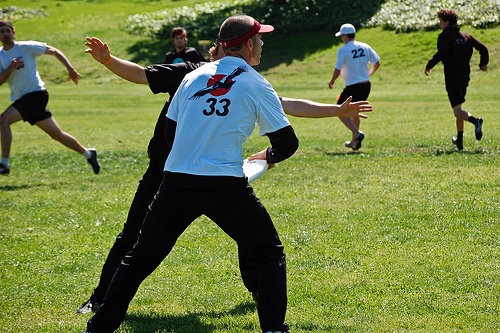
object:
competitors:
[1, 8, 474, 167]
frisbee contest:
[236, 149, 266, 179]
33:
[201, 96, 233, 118]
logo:
[186, 63, 246, 101]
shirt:
[163, 55, 292, 179]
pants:
[83, 169, 289, 331]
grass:
[1, 180, 91, 326]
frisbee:
[242, 156, 270, 184]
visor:
[215, 17, 276, 48]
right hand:
[246, 150, 277, 172]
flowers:
[127, 15, 144, 28]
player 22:
[325, 22, 382, 153]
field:
[296, 156, 498, 332]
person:
[0, 18, 102, 176]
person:
[422, 7, 490, 154]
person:
[161, 26, 207, 66]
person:
[84, 13, 299, 331]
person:
[73, 35, 375, 321]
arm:
[82, 34, 182, 85]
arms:
[276, 93, 374, 120]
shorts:
[7, 89, 53, 127]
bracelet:
[100, 54, 113, 65]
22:
[306, 52, 321, 64]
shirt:
[332, 39, 382, 87]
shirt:
[160, 46, 208, 65]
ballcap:
[334, 22, 356, 37]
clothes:
[423, 23, 491, 76]